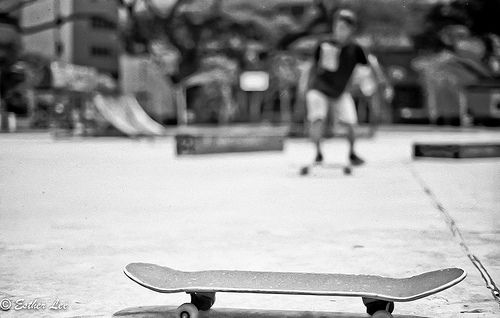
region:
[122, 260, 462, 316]
a black skate board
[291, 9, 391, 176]
a person on a skate board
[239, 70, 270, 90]
a white sign in the background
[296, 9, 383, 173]
a person wearing a black shirt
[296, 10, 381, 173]
a person skate boarding with their arms out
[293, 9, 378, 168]
a person wearing white shorts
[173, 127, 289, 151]
a curb on the ground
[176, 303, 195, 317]
a wheel on the skate board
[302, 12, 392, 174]
a person skate boarding down the street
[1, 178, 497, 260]
the sidewalk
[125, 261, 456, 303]
skateboard is not used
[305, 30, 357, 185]
person on a skateboard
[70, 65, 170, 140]
ramp is empty for skaters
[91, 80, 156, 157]
ramp for skaters to skateboard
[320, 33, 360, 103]
person with dark shirt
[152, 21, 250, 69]
people in the back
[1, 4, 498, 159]
photo is out of focus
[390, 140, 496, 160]
board on the ground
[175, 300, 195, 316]
white wheel on skateboard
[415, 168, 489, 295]
lines on the ground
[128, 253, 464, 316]
skateboard on the ground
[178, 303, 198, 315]
wheel on the skateboard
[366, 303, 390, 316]
white wheel under the board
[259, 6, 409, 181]
boy riding skateboard outside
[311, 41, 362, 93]
the boy's black shirt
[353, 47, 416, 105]
the boy's left arm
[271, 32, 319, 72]
the boy's right arm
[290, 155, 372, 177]
skateboard that the boy is riding on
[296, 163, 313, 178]
wheel on the boy's skateboard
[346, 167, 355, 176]
wheel under the boy's skateboard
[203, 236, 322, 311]
There is a black skateboard visible here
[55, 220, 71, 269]
There is light gray sidewalk that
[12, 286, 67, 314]
The name at the bottom is Esther Lee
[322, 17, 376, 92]
This man has a black t-shirt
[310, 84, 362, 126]
This man is wearing light white shorts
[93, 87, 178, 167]
This man has a skateboarding ramp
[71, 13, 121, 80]
There is a concrete building that is here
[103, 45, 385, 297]
This photo was taken in the summer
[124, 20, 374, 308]
This photo was taken in New York City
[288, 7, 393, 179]
skateboarder wearing black t-shirt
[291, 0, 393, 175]
skateboarder wearing white shorts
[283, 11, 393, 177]
man standing on skateboard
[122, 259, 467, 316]
black skateboard on concrete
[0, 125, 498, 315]
cooncrete with skateboard on top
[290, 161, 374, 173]
skateboard with man on top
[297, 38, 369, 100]
white t-shirt with white logo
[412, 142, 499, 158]
ramp for doing tricks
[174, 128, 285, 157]
ramp for doing tricks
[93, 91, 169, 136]
ramp for doing tricks